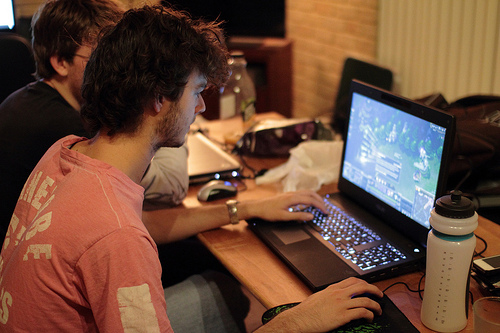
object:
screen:
[340, 91, 451, 231]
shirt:
[0, 135, 176, 333]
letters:
[21, 243, 54, 262]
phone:
[466, 252, 499, 276]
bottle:
[420, 189, 480, 331]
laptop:
[246, 78, 456, 294]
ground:
[358, 131, 383, 168]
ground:
[413, 145, 460, 186]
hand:
[287, 275, 384, 333]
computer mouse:
[196, 177, 239, 203]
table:
[173, 105, 499, 332]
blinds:
[376, 1, 498, 94]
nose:
[193, 93, 206, 114]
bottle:
[216, 47, 258, 151]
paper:
[253, 135, 346, 196]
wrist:
[222, 199, 251, 226]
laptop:
[187, 130, 248, 188]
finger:
[345, 305, 376, 324]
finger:
[345, 294, 383, 316]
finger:
[341, 283, 384, 298]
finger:
[292, 194, 328, 213]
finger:
[336, 276, 369, 289]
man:
[0, 4, 387, 332]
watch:
[223, 198, 241, 225]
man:
[0, 0, 122, 250]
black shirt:
[0, 80, 85, 225]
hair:
[75, 0, 231, 143]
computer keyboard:
[283, 193, 410, 275]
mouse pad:
[258, 288, 420, 332]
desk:
[156, 107, 500, 332]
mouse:
[349, 278, 384, 327]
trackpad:
[264, 207, 317, 247]